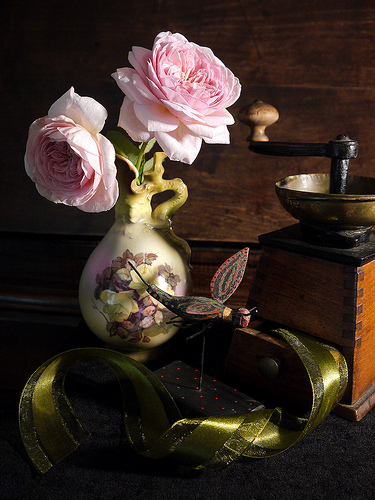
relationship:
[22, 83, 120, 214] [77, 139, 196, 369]
flower in vase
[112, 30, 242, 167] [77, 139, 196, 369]
flower in vase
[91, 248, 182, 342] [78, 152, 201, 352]
decoration on vase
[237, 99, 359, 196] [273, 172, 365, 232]
grinding mill attached to bowl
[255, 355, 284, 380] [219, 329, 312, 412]
knob on drawer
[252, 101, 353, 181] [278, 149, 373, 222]
crank attached to bowl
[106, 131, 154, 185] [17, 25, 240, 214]
leaf of plant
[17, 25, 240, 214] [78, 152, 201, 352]
plant in vase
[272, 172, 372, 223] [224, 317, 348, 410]
bowl on top of drawer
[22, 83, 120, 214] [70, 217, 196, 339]
flower in vase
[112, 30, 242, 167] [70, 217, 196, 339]
flower in vase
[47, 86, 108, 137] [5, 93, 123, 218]
flower petal of flower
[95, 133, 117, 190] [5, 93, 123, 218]
flower petal of flower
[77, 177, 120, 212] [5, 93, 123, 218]
flower petal of flower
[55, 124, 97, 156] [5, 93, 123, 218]
petal of flower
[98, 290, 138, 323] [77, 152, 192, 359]
flower painted on vase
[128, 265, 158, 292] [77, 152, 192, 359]
flower painted on vase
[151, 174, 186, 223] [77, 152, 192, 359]
handle on vase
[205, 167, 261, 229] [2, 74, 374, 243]
grain on wood